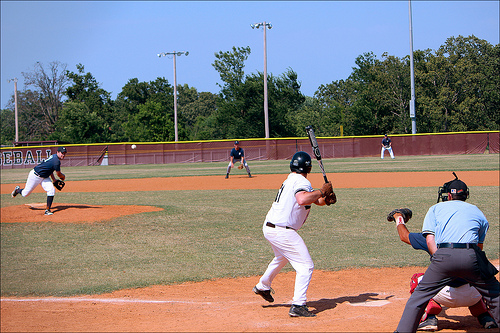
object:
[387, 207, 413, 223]
mitt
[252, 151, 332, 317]
batter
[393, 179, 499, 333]
umpire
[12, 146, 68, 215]
player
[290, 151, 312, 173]
helmet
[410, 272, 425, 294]
kneepad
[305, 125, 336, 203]
bat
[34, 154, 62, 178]
shirt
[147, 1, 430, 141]
light pole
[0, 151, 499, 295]
grass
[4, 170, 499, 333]
sand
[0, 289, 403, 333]
line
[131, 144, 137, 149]
ball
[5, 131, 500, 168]
fence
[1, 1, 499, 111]
sky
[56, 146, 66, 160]
hat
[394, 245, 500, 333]
pant